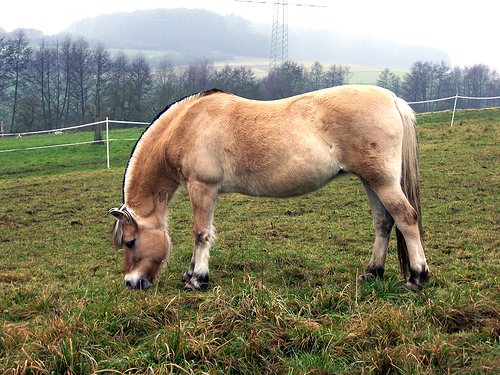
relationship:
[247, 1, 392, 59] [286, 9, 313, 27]
light in sky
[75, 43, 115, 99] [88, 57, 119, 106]
haze on tree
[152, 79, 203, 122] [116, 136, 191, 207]
mane on neck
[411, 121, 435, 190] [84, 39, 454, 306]
tail of horse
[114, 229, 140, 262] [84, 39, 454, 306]
eye on horse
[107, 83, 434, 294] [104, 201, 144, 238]
horse has ear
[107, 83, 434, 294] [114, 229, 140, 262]
horse has eye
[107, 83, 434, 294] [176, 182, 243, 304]
horse has leg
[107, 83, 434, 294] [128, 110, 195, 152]
horse has hair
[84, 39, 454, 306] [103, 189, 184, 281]
animal has head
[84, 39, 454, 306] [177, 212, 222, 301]
donkey has hoof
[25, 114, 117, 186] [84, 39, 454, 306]
fence keeping animal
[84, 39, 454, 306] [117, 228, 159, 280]
donkey has face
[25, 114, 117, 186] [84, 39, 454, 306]
fence keep horse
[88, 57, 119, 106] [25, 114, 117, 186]
tree on other side of fence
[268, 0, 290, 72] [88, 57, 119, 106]
object behind tree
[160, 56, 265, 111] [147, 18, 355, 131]
hill in background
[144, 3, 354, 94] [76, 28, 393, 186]
fog in distance